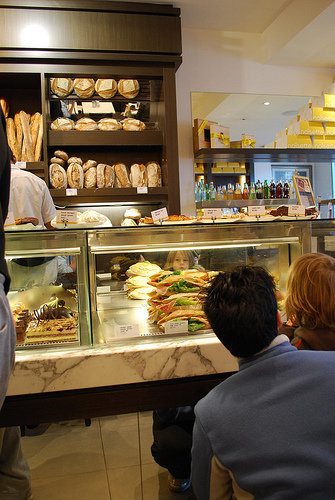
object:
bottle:
[214, 183, 224, 200]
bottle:
[234, 182, 243, 202]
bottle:
[256, 179, 263, 201]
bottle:
[269, 178, 276, 199]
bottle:
[282, 180, 288, 199]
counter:
[193, 197, 299, 207]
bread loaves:
[48, 162, 67, 189]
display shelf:
[42, 65, 177, 192]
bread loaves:
[96, 163, 116, 187]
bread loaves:
[131, 162, 148, 188]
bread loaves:
[50, 117, 76, 132]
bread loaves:
[122, 117, 146, 132]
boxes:
[313, 91, 334, 111]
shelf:
[193, 145, 335, 159]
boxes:
[290, 119, 325, 135]